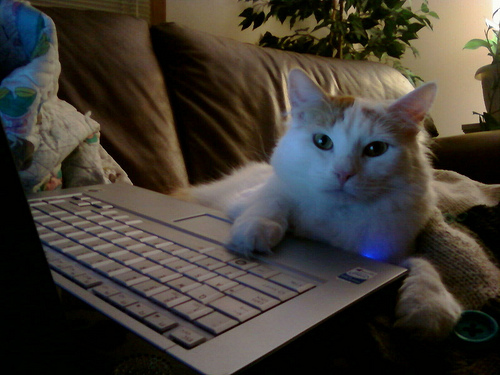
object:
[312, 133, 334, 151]
eye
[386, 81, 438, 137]
ear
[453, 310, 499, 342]
button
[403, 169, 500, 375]
sweater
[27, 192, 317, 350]
keyboard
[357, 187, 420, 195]
whiskers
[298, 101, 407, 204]
face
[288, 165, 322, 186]
white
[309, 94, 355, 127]
orange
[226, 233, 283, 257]
paw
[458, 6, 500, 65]
plant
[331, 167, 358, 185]
nose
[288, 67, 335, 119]
ear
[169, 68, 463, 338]
cat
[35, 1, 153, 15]
blinds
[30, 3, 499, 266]
brown couch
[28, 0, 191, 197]
couch cushions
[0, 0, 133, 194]
blanket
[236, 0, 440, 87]
leaves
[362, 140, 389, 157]
eye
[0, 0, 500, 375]
photo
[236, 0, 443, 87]
plant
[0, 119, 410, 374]
computer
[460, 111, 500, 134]
table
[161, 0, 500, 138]
wall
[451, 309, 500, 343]
soda lid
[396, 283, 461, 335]
cat's paw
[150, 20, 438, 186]
cushion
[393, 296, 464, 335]
paw